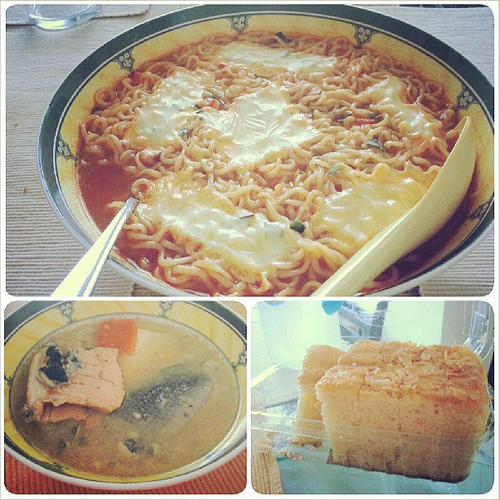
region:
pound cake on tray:
[294, 340, 489, 483]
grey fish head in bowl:
[123, 367, 210, 443]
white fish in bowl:
[30, 348, 121, 406]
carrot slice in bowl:
[98, 319, 136, 351]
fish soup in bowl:
[21, 320, 237, 478]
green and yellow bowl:
[4, 302, 254, 490]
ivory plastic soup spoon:
[314, 118, 479, 296]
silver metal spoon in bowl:
[46, 195, 138, 299]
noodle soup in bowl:
[45, 6, 495, 288]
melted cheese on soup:
[203, 88, 316, 165]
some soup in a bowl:
[75, 27, 462, 293]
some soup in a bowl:
[12, 315, 232, 480]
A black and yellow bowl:
[1, 300, 243, 490]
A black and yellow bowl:
[36, 5, 491, 295]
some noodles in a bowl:
[80, 30, 460, 292]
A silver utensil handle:
[55, 191, 140, 291]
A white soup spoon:
[305, 116, 470, 293]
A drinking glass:
[22, 1, 102, 32]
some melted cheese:
[134, 44, 435, 269]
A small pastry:
[292, 335, 487, 485]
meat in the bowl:
[56, 369, 116, 414]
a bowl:
[204, 313, 239, 348]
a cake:
[327, 371, 464, 430]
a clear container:
[266, 415, 322, 452]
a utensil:
[97, 210, 133, 243]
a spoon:
[436, 137, 466, 197]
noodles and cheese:
[139, 84, 357, 229]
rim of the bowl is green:
[34, 123, 56, 140]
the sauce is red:
[92, 175, 121, 206]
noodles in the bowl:
[161, 243, 205, 283]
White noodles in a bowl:
[83, 114, 129, 152]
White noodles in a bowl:
[130, 144, 175, 193]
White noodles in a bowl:
[133, 226, 188, 276]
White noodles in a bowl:
[190, 243, 244, 289]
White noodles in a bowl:
[253, 266, 308, 298]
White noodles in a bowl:
[293, 216, 340, 286]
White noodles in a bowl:
[266, 176, 325, 225]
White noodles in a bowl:
[215, 159, 283, 214]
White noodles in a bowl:
[313, 101, 393, 191]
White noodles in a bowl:
[206, 48, 268, 105]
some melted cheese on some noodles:
[130, 40, 435, 270]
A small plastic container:
[253, 299, 490, 488]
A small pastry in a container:
[291, 335, 491, 474]